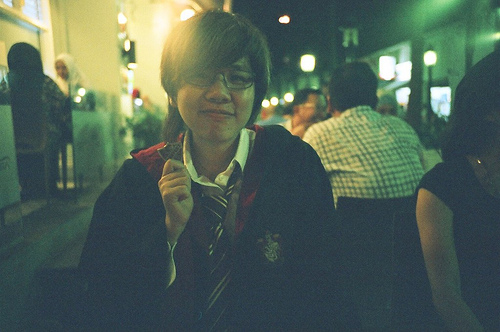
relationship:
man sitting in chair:
[77, 10, 347, 332] [20, 261, 84, 330]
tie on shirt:
[195, 184, 235, 329] [175, 139, 246, 176]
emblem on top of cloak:
[257, 231, 282, 263] [76, 123, 343, 332]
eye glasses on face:
[180, 64, 257, 89] [180, 52, 255, 144]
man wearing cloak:
[77, 10, 347, 332] [245, 110, 339, 325]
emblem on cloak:
[257, 231, 282, 263] [78, 124, 332, 320]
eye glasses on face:
[180, 64, 257, 89] [177, 53, 250, 142]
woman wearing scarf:
[53, 47, 91, 104] [49, 51, 81, 94]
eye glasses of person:
[180, 64, 257, 89] [170, 34, 310, 276]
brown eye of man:
[187, 69, 207, 80] [77, 10, 347, 332]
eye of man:
[215, 73, 255, 93] [77, 10, 347, 332]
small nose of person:
[203, 72, 232, 103] [91, 10, 338, 327]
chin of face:
[192, 120, 234, 142] [155, 5, 267, 144]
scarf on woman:
[66, 48, 97, 83] [31, 40, 117, 103]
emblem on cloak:
[257, 231, 282, 263] [76, 123, 343, 332]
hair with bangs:
[165, 22, 289, 64] [180, 43, 250, 72]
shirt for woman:
[413, 150, 498, 325] [82, 8, 340, 329]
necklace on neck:
[476, 152, 498, 181] [479, 128, 499, 199]